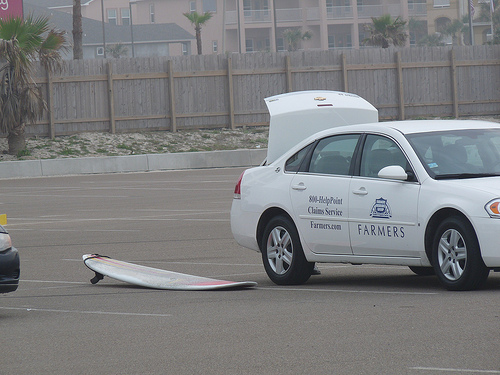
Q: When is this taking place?
A: Daytime.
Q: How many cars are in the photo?
A: Two.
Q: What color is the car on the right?
A: White.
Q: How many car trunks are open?
A: One.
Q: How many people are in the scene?
A: None.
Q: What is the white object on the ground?
A: Surfboard.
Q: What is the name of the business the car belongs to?
A: Farmers.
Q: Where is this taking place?
A: In a parking lot.